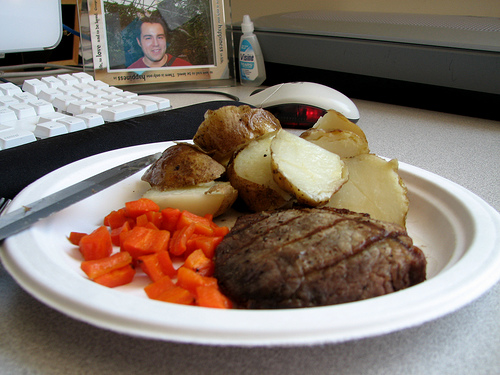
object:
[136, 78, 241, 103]
tail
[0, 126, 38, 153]
keyboard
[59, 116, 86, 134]
key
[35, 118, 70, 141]
key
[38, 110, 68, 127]
key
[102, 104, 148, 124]
key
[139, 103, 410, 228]
potato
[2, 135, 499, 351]
plate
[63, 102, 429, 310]
food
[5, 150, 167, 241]
knife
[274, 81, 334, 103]
white top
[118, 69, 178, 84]
words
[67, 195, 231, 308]
cooked carrots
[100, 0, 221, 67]
photo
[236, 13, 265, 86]
bottle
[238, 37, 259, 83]
label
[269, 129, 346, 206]
potato chunks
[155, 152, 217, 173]
skin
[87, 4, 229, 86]
frame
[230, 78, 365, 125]
computer mouse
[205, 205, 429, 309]
hamburger steak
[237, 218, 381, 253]
grill marks